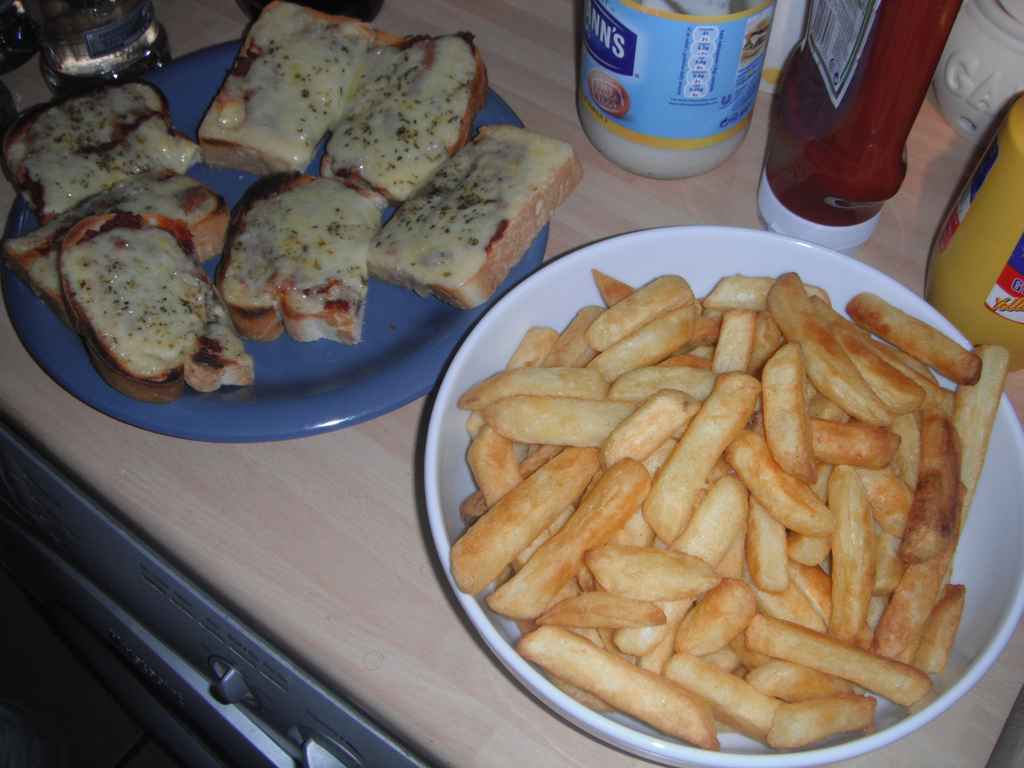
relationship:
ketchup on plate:
[771, 0, 940, 250] [5, 0, 1024, 768]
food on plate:
[58, 58, 968, 629] [68, 72, 928, 568]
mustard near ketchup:
[929, 61, 1022, 345] [771, 0, 940, 250]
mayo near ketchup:
[571, 0, 768, 207] [771, 0, 940, 250]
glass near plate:
[27, 0, 189, 87] [68, 72, 928, 568]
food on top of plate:
[58, 58, 968, 629] [68, 72, 928, 568]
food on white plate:
[58, 58, 968, 629] [68, 72, 928, 568]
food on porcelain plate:
[58, 58, 968, 629] [68, 72, 928, 568]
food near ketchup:
[58, 58, 968, 629] [771, 0, 940, 250]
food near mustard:
[58, 58, 968, 629] [929, 61, 1022, 345]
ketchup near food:
[771, 0, 940, 250] [58, 58, 968, 629]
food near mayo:
[58, 58, 968, 629] [571, 0, 768, 207]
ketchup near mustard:
[771, 0, 940, 250] [929, 61, 1022, 345]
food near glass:
[58, 58, 968, 629] [27, 0, 189, 87]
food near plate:
[58, 58, 968, 629] [68, 72, 928, 568]